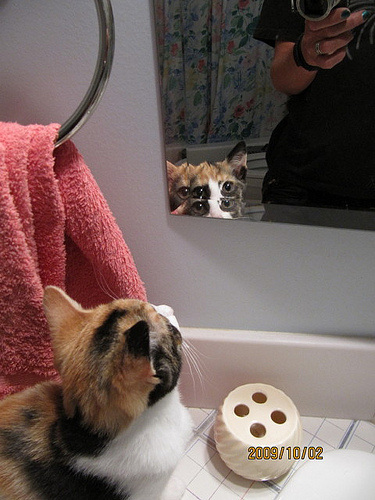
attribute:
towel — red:
[0, 119, 148, 402]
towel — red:
[4, 130, 150, 378]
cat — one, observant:
[25, 289, 186, 485]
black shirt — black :
[262, 70, 373, 208]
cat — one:
[182, 150, 271, 219]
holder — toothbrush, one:
[197, 361, 329, 491]